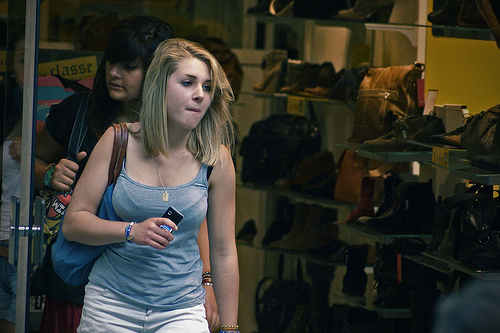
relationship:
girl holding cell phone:
[60, 33, 251, 332] [153, 205, 183, 239]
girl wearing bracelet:
[60, 33, 251, 332] [123, 218, 138, 244]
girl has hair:
[60, 33, 251, 332] [132, 34, 242, 176]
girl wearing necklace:
[60, 33, 251, 332] [146, 136, 190, 204]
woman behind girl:
[21, 17, 177, 330] [60, 33, 251, 332]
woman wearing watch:
[21, 17, 177, 330] [39, 162, 56, 191]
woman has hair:
[21, 17, 177, 330] [83, 17, 175, 127]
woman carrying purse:
[21, 17, 177, 330] [50, 69, 101, 181]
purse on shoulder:
[50, 69, 101, 181] [57, 87, 110, 119]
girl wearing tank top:
[60, 33, 251, 332] [88, 137, 210, 313]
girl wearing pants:
[60, 33, 251, 332] [73, 276, 218, 332]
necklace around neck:
[146, 136, 190, 204] [142, 101, 192, 160]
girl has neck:
[60, 33, 251, 332] [142, 101, 192, 160]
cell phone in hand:
[153, 205, 183, 239] [131, 214, 180, 250]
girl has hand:
[60, 33, 251, 332] [131, 214, 180, 250]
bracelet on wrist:
[123, 218, 138, 244] [121, 216, 138, 245]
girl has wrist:
[60, 33, 251, 332] [121, 216, 138, 245]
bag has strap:
[43, 114, 127, 296] [108, 116, 132, 187]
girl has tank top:
[60, 33, 251, 332] [88, 137, 210, 313]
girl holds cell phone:
[60, 33, 251, 332] [153, 205, 183, 239]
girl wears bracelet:
[60, 33, 251, 332] [123, 218, 138, 244]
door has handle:
[0, 3, 42, 331] [6, 192, 47, 270]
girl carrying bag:
[60, 33, 251, 332] [43, 114, 127, 296]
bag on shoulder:
[43, 114, 127, 296] [100, 115, 146, 144]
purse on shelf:
[232, 104, 323, 196] [210, 162, 363, 213]